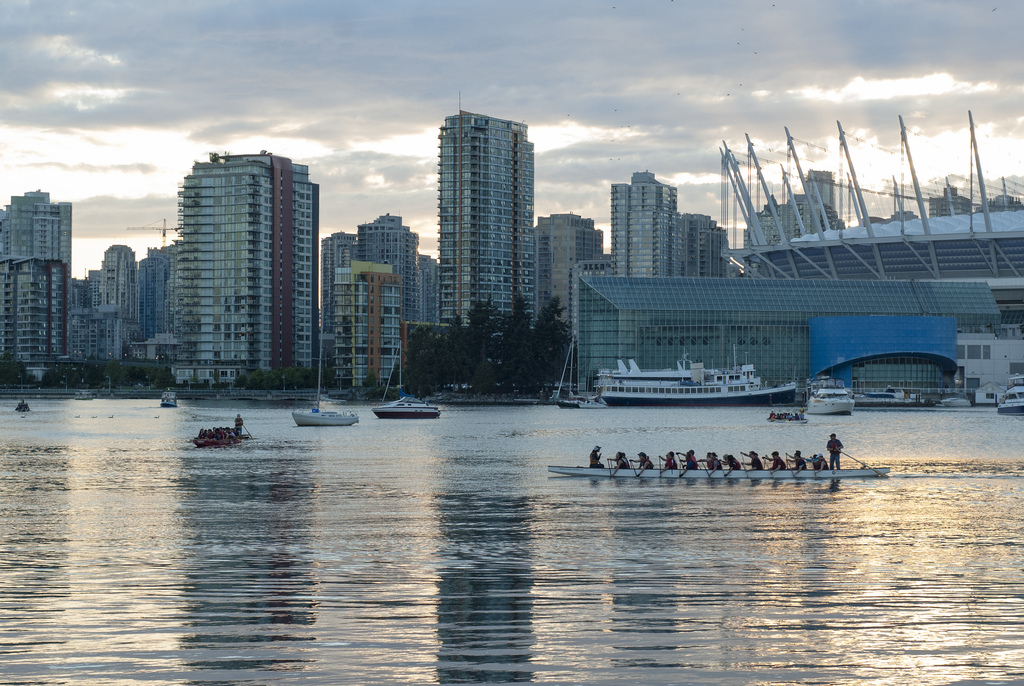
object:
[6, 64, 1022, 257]
skyline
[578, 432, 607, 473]
people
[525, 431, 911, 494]
canoe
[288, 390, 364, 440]
boat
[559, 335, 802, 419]
boat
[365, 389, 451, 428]
boat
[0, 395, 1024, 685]
lake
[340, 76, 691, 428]
middle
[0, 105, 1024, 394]
building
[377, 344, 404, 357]
windows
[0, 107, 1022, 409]
background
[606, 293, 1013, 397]
wall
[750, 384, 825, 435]
boats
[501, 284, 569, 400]
tree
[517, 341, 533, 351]
leaves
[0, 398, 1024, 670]
water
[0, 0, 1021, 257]
sky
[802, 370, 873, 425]
boat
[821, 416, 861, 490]
man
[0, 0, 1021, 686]
picture